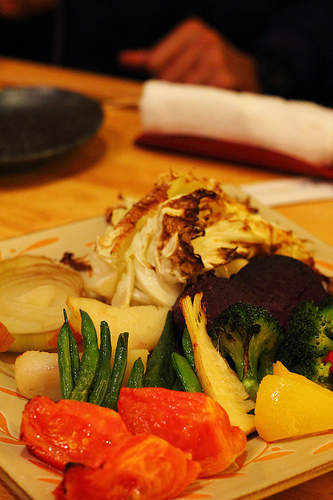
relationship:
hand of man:
[139, 28, 191, 58] [0, 0, 309, 101]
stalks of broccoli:
[197, 298, 329, 382] [215, 297, 291, 373]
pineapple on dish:
[109, 267, 175, 354] [0, 177, 332, 499]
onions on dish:
[21, 251, 101, 341] [0, 177, 332, 499]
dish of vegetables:
[0, 177, 332, 499] [53, 245, 268, 434]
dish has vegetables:
[44, 206, 121, 265] [53, 245, 268, 434]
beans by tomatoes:
[53, 304, 133, 380] [91, 406, 196, 482]